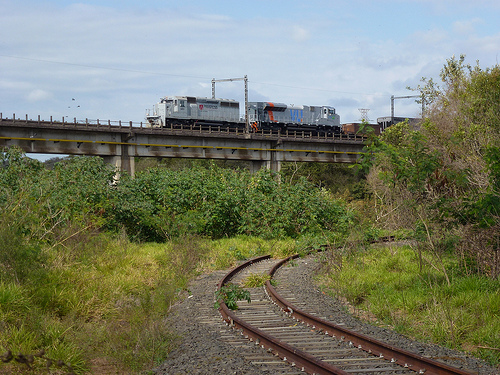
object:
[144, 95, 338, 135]
train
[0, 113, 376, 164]
bridge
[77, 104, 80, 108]
bird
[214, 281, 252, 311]
weed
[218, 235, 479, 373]
railroad track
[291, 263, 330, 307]
gravel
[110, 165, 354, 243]
bushes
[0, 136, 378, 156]
yellow line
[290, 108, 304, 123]
blue marks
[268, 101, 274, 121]
red stripe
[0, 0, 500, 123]
sky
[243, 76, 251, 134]
height pole